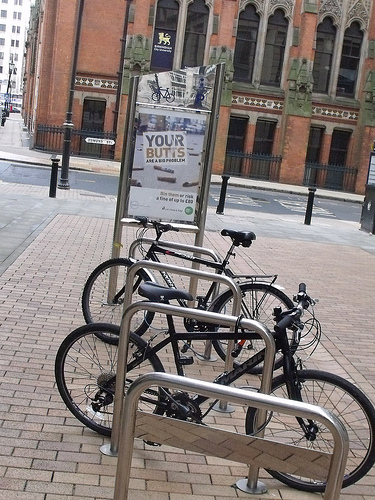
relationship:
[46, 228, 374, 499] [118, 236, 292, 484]
bikes on racks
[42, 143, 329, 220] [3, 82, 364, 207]
fence in background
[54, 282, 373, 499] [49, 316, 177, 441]
bikes has large wheel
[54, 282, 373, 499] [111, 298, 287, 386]
bikes chained to rack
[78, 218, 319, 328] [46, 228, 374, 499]
bike on sidewalk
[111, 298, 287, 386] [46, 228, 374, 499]
rack on sidewalk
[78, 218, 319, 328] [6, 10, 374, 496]
bike standing outside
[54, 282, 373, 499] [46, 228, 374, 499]
bikes on sidewalk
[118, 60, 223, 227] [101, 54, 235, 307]
sign on metal post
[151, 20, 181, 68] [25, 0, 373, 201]
banner on building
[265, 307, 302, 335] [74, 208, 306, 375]
handle of bike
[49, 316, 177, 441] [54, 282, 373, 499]
wheel of bikes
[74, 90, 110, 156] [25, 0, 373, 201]
door of building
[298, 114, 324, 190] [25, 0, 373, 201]
door of building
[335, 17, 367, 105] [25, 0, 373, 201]
window of building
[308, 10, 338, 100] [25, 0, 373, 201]
window of building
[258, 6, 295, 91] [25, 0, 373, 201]
window of building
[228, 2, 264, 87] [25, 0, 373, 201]
window of building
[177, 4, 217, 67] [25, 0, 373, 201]
window of building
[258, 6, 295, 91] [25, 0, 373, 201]
window on building